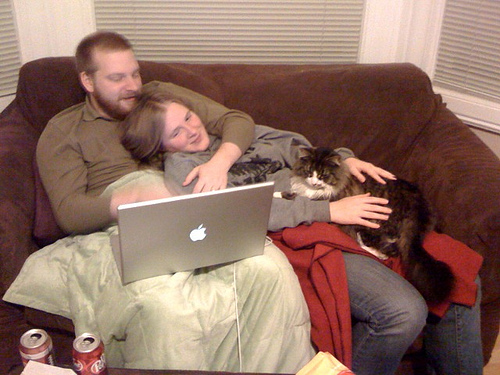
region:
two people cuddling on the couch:
[34, 28, 489, 373]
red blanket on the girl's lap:
[268, 221, 484, 366]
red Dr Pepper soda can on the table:
[71, 330, 106, 373]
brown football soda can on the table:
[18, 326, 55, 370]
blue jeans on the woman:
[343, 249, 487, 374]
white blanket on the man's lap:
[1, 167, 318, 372]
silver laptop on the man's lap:
[106, 175, 279, 286]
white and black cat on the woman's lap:
[272, 143, 456, 304]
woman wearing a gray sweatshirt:
[161, 120, 357, 227]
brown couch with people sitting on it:
[1, 54, 498, 374]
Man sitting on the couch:
[37, 29, 309, 374]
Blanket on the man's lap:
[3, 167, 313, 374]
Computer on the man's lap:
[109, 178, 274, 285]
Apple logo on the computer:
[189, 223, 207, 243]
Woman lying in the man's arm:
[123, 89, 484, 374]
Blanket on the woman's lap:
[268, 218, 484, 368]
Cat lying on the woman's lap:
[288, 142, 458, 303]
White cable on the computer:
[233, 234, 273, 374]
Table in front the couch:
[6, 366, 298, 373]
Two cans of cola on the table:
[18, 328, 105, 374]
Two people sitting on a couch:
[1, 27, 499, 371]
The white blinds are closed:
[1, 2, 499, 109]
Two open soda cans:
[15, 325, 111, 373]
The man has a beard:
[69, 29, 147, 126]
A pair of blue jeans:
[338, 247, 485, 373]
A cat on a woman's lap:
[122, 92, 483, 312]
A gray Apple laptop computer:
[105, 178, 275, 286]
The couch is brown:
[1, 53, 498, 373]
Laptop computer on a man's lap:
[36, 29, 295, 291]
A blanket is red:
[263, 218, 485, 370]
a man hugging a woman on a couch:
[36, 32, 481, 374]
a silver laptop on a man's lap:
[108, 181, 273, 284]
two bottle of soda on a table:
[17, 330, 107, 374]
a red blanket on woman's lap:
[266, 221, 482, 371]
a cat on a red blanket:
[291, 143, 451, 307]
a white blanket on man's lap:
[4, 223, 313, 373]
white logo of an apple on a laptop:
[188, 223, 205, 242]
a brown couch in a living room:
[0, 58, 499, 373]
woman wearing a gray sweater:
[163, 122, 355, 232]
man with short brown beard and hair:
[73, 34, 143, 117]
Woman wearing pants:
[332, 236, 499, 371]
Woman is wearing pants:
[335, 245, 490, 373]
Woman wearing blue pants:
[332, 240, 488, 372]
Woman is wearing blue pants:
[328, 242, 485, 374]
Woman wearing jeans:
[308, 237, 488, 373]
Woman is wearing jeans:
[331, 228, 491, 373]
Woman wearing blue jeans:
[332, 233, 484, 373]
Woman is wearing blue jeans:
[324, 223, 487, 373]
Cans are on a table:
[14, 321, 110, 372]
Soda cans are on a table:
[13, 326, 113, 371]